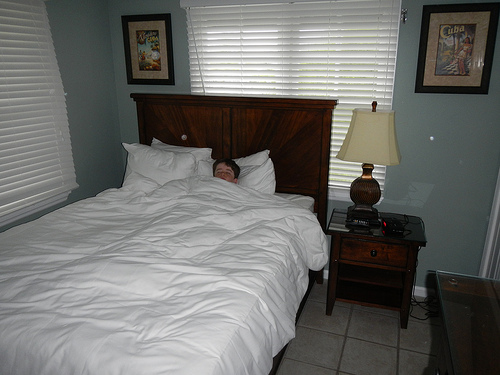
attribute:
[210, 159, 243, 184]
boy — sleeping, young, small, asleep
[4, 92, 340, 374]
bed — large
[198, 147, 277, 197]
pillow — white, fluffy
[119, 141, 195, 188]
pillow — white, fluffy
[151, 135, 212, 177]
pillow — white, fluffy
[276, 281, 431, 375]
floor — tile, beige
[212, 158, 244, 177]
hair — short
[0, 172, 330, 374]
bed cover — white, fluffy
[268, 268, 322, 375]
frame — wood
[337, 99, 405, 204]
lamp — off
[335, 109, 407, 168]
lampshade — ivory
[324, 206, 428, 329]
table — wooden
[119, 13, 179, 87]
picture — hanging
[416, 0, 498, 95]
picture — hanging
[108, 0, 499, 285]
wall — grey-blue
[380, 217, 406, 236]
alarm clock — small, black, digital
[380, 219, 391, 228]
numbers — red, glowing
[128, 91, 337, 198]
headboard — large, dark brown, tall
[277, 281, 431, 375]
tile — light colored, brown, beige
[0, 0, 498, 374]
picture — taken indoors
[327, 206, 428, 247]
top — glass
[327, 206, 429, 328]
nightstand — glass covered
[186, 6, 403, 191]
window — large, covered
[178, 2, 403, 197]
mini blinds — white, shut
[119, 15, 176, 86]
frame — black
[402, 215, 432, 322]
cord — electrical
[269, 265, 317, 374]
bed frame — wood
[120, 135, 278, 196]
pillows — fluffy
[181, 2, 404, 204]
shade — white, shut